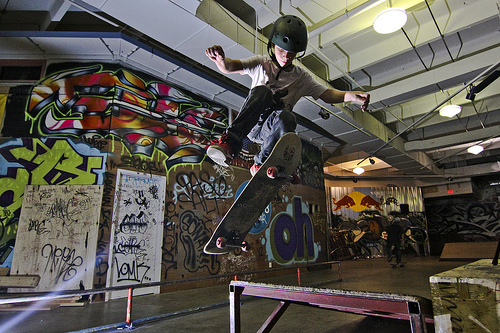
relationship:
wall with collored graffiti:
[3, 29, 345, 305] [2, 60, 229, 265]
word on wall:
[268, 204, 318, 269] [283, 173, 325, 201]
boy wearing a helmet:
[204, 15, 370, 176] [265, 13, 307, 65]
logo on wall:
[331, 193, 358, 210] [328, 181, 426, 246]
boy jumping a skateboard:
[204, 15, 370, 176] [198, 131, 306, 258]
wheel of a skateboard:
[266, 165, 279, 179] [246, 136, 305, 261]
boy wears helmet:
[204, 15, 370, 176] [258, 13, 308, 48]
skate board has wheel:
[203, 132, 303, 254] [268, 164, 279, 177]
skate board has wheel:
[203, 132, 303, 254] [293, 173, 300, 185]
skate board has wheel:
[203, 132, 303, 254] [216, 236, 228, 248]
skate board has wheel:
[203, 132, 303, 254] [241, 241, 251, 251]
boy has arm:
[204, 15, 370, 176] [205, 41, 260, 78]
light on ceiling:
[435, 95, 469, 126] [51, 3, 498, 169]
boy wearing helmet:
[189, 9, 380, 181] [258, 14, 304, 50]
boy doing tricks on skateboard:
[204, 15, 370, 176] [200, 6, 373, 176]